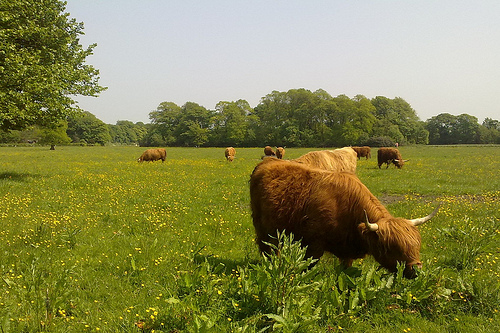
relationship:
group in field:
[138, 146, 439, 282] [0, 144, 499, 332]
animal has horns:
[248, 157, 438, 279] [359, 200, 443, 233]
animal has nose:
[248, 157, 438, 279] [402, 266, 424, 279]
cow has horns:
[377, 146, 413, 170] [395, 156, 410, 165]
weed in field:
[126, 259, 146, 282] [0, 144, 498, 332]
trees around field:
[1, 2, 497, 150] [0, 144, 498, 332]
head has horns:
[361, 208, 436, 280] [359, 200, 443, 233]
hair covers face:
[375, 220, 431, 253] [375, 221, 428, 277]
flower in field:
[55, 305, 79, 323] [0, 144, 498, 332]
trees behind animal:
[1, 2, 497, 150] [248, 157, 438, 279]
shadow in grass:
[179, 253, 292, 318] [3, 143, 499, 332]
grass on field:
[3, 143, 499, 332] [0, 144, 499, 332]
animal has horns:
[250, 157, 444, 279] [359, 200, 443, 233]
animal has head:
[250, 157, 444, 279] [361, 208, 436, 280]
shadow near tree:
[2, 169, 49, 190] [1, 0, 108, 133]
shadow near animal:
[179, 253, 292, 318] [250, 157, 444, 279]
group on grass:
[138, 146, 439, 282] [3, 143, 499, 332]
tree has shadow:
[1, 0, 108, 133] [2, 169, 49, 190]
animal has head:
[248, 157, 438, 279] [361, 208, 436, 280]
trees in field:
[1, 2, 497, 150] [0, 144, 498, 332]